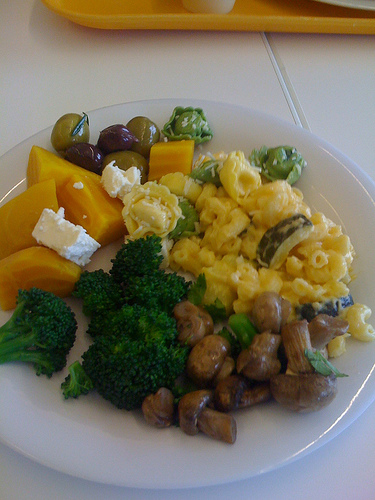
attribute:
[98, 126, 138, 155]
olive — black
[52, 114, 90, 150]
olive — green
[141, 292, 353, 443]
mushrooms — sauteed, brown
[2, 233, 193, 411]
broccoli — green, steamed, beautiful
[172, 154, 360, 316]
macaroni and cheese — yellow, creamy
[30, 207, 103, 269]
feta cheese — white, crumbly, small, chunky, like cream cheese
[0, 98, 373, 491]
plate — dinner plate, white, round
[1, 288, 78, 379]
broccoli floret — steamed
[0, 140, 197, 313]
winter squash — steamed, sweet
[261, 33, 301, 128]
caulk — white, in a line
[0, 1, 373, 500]
table — white, tile, beautiful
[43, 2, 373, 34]
tray — yellow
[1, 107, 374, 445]
food — colorful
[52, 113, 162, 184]
olives — different colors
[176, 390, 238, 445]
mushroom — brown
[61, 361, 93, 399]
broccoli floret — tiny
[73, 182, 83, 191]
crumb — tiny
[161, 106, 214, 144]
pasta — green, like bussel sprout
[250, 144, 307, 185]
pasta — like bussel sprout